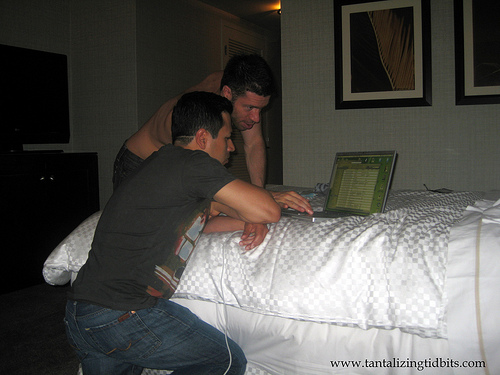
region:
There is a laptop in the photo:
[71, 43, 436, 370]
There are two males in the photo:
[78, 41, 386, 362]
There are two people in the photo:
[79, 49, 311, 371]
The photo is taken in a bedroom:
[20, 23, 455, 358]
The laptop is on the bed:
[222, 121, 447, 328]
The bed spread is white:
[78, 141, 488, 368]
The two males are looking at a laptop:
[98, 34, 411, 372]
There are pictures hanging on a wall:
[273, 9, 496, 171]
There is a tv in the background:
[15, 31, 223, 254]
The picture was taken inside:
[30, 24, 481, 348]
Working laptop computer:
[277, 148, 398, 225]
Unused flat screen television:
[1, 46, 72, 146]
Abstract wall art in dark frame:
[332, 5, 431, 105]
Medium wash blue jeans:
[62, 300, 204, 371]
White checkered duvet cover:
[282, 231, 442, 330]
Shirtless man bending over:
[119, 51, 266, 181]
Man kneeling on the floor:
[71, 90, 253, 372]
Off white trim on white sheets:
[465, 221, 494, 373]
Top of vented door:
[222, 25, 269, 60]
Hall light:
[264, 0, 282, 16]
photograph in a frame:
[330, 2, 437, 108]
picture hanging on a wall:
[452, 1, 499, 106]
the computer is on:
[282, 145, 398, 222]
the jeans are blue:
[58, 295, 253, 374]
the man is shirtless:
[114, 48, 309, 215]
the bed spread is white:
[49, 171, 475, 332]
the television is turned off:
[1, 43, 76, 153]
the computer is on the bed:
[274, 144, 399, 226]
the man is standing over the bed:
[112, 47, 306, 212]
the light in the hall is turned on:
[251, 0, 299, 27]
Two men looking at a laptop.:
[55, 22, 437, 343]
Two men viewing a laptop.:
[75, 30, 445, 345]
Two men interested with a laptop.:
[65, 30, 420, 355]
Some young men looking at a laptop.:
[40, 15, 430, 355]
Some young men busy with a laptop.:
[45, 26, 415, 346]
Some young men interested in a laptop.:
[40, 0, 450, 325]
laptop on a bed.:
[310, 130, 405, 230]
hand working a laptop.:
[275, 136, 400, 222]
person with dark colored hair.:
[230, 45, 281, 130]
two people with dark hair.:
[170, 45, 281, 178]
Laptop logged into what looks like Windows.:
[302, 147, 422, 224]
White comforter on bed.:
[315, 228, 474, 339]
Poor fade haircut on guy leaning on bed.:
[170, 133, 205, 156]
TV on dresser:
[1, 53, 78, 160]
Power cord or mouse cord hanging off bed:
[212, 228, 251, 374]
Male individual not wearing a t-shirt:
[105, 65, 273, 139]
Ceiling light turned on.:
[243, 1, 293, 40]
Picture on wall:
[327, 0, 434, 107]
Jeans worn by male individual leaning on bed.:
[57, 298, 222, 369]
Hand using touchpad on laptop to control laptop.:
[275, 186, 317, 219]